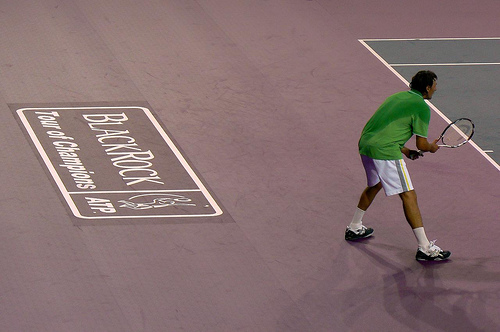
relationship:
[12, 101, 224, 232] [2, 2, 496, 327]
logo on a court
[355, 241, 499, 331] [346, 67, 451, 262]
shadow of tennis player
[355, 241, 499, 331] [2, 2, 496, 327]
shadow on court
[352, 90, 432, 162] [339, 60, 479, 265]
shirt of player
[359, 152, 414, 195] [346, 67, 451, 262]
shorts of tennis player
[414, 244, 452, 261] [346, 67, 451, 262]
shoe of tennis player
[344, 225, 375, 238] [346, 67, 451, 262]
shoe of tennis player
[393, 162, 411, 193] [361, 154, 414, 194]
stripe on shorts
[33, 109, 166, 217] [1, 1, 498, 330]
letters on tennis court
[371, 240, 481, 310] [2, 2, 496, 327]
shadow on court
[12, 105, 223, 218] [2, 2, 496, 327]
logo on court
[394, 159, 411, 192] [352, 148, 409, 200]
stripe on shorts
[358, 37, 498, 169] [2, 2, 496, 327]
lines on court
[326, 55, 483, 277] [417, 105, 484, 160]
man holding tennis racket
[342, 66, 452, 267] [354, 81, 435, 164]
man wearing a shirt